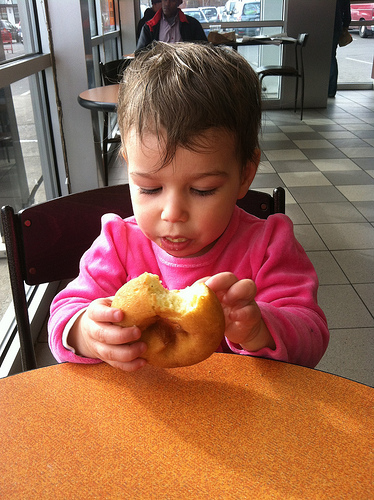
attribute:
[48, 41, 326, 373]
child — girl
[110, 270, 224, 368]
donut — cake donut, yellow, plain, bitten, brown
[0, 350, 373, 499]
table — orange, brownish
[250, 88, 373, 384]
floor — tile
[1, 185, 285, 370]
chair — metal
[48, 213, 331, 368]
shirt — pink, a sweater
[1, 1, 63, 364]
window — large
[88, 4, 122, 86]
window — large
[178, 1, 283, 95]
window — large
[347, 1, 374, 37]
vehicle — red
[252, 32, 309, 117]
chair — black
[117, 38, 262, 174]
hair — brown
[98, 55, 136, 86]
chair — brown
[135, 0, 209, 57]
man — holding something